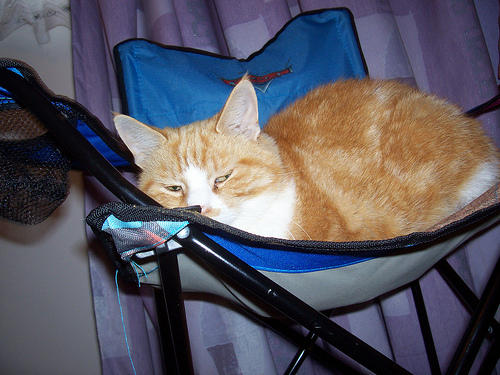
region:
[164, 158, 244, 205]
The eyes of this cat are a very light green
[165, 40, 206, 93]
This chair is a very deep blue color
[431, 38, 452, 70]
This curtain is a very light purple color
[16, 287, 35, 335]
The color of this wall is a very off white color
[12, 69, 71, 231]
There is a mesh container for a can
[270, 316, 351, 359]
There is black aluminum supporting the chari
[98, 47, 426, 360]
Jackson Mingus took this photo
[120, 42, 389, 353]
This took place in the city of Dayton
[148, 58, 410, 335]
This took place in the state of Ohio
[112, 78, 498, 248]
the cat lying on the chair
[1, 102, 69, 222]
the net for the cup holder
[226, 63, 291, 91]
the logo on the blue chair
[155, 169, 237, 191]
the cat's two eyes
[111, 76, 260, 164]
the cat's ears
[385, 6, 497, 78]
the purple curtain in the back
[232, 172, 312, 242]
the whiskers on the cat's face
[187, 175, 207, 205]
the white spot on the cat's nose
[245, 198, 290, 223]
the white spot on the cat's neck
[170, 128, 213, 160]
the stripes on the top of the cat's head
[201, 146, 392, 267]
orange and white furry cat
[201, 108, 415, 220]
orange and white furry cat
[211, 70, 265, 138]
the ear of a cat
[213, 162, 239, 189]
the eye of a cat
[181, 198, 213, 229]
the nose of a cat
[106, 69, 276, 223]
the head of a cat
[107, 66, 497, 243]
an orange and white cat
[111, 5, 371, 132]
a blue and black seat back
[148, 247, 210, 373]
a black seat leg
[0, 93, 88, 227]
a mesh cupholder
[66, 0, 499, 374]
gray curtains behind the chair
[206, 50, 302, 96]
a logo on the chair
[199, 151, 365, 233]
a cat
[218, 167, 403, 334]
a cat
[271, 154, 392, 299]
a cat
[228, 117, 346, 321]
a cat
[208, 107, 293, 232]
a cat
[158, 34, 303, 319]
a cat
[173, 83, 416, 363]
a cat